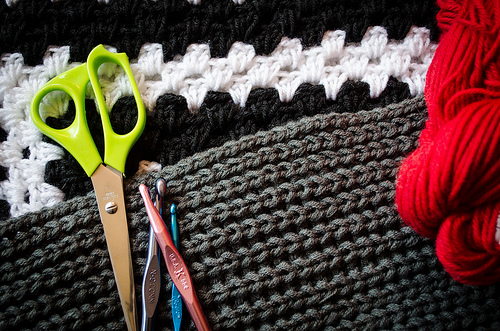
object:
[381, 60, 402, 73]
yarn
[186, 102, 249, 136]
design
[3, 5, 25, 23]
yarn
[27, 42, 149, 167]
handle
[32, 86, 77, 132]
fingerhole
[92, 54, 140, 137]
fingerhole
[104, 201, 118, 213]
screw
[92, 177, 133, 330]
blades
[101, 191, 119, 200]
writing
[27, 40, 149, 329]
scissors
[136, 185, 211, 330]
needle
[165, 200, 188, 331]
needle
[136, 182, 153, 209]
end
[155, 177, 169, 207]
end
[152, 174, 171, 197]
ball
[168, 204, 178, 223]
end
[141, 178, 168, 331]
needles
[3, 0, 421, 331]
blanket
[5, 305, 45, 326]
yarn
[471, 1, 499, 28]
yarn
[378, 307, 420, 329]
gray yarn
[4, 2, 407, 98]
crochet work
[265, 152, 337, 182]
crochet design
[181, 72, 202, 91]
stitching